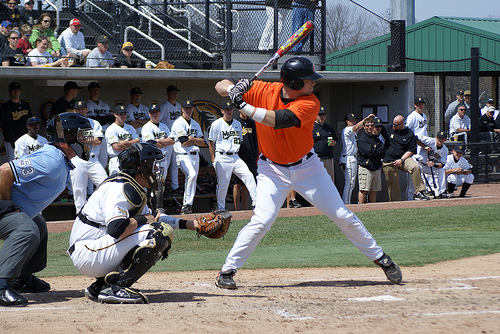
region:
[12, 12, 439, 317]
a baseball game underway.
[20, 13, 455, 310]
a baseball game in the daytime.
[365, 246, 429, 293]
a left foot planted on the ground.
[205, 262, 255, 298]
right foot planted on the ground.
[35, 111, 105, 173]
man wearing face protection.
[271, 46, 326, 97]
man wearing head protection.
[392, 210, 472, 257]
green patch of grass on field.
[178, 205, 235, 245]
left hand with catcher's mitt.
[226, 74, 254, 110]
dark gloves holding a baseball bat.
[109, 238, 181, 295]
person wearing shin guards.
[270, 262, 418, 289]
man's shadow in dirt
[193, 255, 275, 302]
batter's black sneakers with white logo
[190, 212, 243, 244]
brown baseball in catcher's hand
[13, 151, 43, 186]
white number on blue jersey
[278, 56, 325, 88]
black shiny baseball helmet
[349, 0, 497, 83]
green domed roof on building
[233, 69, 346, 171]
man wearing orange jersey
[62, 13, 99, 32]
red and white cap on man's head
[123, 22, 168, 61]
silver railing in the stands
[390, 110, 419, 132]
shine on man's bald head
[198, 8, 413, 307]
Player wears orange t-shirt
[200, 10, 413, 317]
Batter is in position to hit the ball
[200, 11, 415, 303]
Batter hold bat with two hands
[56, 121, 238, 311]
Catcher is crouched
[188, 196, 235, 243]
Glove is brown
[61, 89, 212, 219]
Players are crossed arms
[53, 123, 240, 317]
catcher wears a helmet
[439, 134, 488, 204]
Player is crouched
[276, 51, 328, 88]
Helmet is black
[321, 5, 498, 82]
Roof is green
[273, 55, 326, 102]
Man is wearing black helmet.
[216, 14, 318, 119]
Man is holding baseball bat.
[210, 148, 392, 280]
Man is wearing white pants.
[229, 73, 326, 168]
Man is wearing orange shirt.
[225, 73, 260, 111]
Man is wearing gloves.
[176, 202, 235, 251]
Catcher is wearing baseball mitt.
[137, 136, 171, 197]
Catcher is wearing face guard.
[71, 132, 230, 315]
Catcher is crouching down.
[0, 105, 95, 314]
Umpire is crouching down behind Catcher.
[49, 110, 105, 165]
Umpire is wearing face guard.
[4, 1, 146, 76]
some fans in a crowd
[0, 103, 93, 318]
the umpire in blue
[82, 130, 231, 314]
the catcher in white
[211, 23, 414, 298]
the batter in orange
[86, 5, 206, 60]
a baseball field's bleachers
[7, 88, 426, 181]
a baseball team in a dugout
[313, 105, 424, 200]
baseball coaches talking to each other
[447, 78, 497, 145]
a small crowd off to the side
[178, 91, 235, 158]
the baseball teams logo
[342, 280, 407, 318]
the white home plate